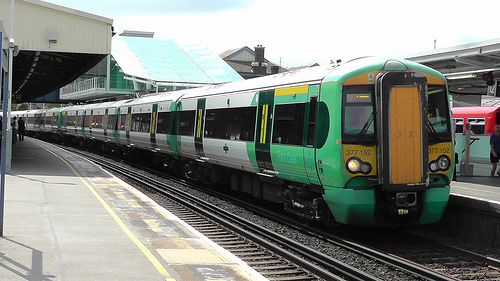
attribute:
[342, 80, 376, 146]
window — pictured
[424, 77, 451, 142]
window — pictured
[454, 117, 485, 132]
windows — pictured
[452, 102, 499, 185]
train — red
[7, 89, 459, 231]
train — metal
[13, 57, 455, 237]
train — green, yellow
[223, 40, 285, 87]
building — pictured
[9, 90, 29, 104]
sign — Platform 14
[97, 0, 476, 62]
sky — blue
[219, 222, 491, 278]
tracks — train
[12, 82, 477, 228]
train — long, green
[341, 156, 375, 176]
headlight — on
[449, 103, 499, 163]
train — red 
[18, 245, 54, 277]
shadow — railing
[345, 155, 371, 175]
lights — pictured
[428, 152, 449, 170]
lights — pictured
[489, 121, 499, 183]
man — pictured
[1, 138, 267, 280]
platform — pictured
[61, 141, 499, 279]
train track — metallic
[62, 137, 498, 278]
track — train, metallic